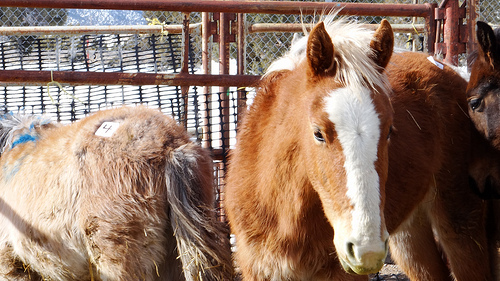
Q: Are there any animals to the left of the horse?
A: Yes, there is an animal to the left of the horse.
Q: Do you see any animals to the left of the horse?
A: Yes, there is an animal to the left of the horse.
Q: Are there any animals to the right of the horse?
A: No, the animal is to the left of the horse.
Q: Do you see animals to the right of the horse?
A: No, the animal is to the left of the horse.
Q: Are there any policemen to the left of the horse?
A: No, there is an animal to the left of the horse.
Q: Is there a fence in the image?
A: Yes, there is a fence.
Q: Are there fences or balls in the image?
A: Yes, there is a fence.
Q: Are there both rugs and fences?
A: No, there is a fence but no rugs.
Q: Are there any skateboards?
A: No, there are no skateboards.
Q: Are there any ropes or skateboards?
A: No, there are no skateboards or ropes.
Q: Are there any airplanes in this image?
A: No, there are no airplanes.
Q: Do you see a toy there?
A: No, there are no toys.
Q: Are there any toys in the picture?
A: No, there are no toys.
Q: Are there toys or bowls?
A: No, there are no toys or bowls.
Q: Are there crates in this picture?
A: No, there are no crates.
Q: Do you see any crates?
A: No, there are no crates.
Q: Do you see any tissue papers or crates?
A: No, there are no crates or tissue papers.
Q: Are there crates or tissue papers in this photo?
A: No, there are no crates or tissue papers.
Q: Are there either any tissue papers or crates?
A: No, there are no crates or tissue papers.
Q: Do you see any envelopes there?
A: No, there are no envelopes.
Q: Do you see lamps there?
A: No, there are no lamps.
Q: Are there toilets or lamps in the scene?
A: No, there are no lamps or toilets.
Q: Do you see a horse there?
A: Yes, there is a horse.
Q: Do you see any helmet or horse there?
A: Yes, there is a horse.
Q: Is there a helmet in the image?
A: No, there are no helmets.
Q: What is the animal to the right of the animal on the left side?
A: The animal is a horse.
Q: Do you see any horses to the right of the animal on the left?
A: Yes, there is a horse to the right of the animal.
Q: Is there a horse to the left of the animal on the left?
A: No, the horse is to the right of the animal.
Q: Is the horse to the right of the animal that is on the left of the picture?
A: Yes, the horse is to the right of the animal.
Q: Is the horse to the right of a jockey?
A: No, the horse is to the right of the animal.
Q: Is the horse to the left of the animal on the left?
A: No, the horse is to the right of the animal.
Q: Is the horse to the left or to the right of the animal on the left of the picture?
A: The horse is to the right of the animal.